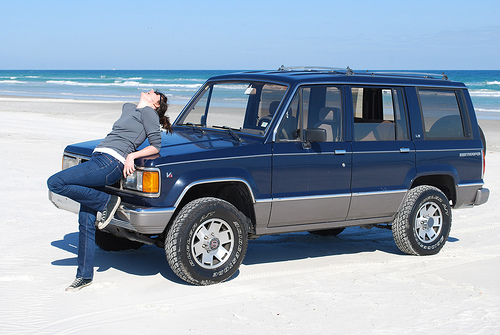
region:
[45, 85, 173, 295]
woman leaning on the hood of a blue vehicle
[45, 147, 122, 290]
blue jeans on a woman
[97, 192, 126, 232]
black shoe on a woman's feet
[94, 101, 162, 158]
gray long sleeve shirt on a woman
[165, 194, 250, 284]
front car wheel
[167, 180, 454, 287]
two car wheels on a blue vehicle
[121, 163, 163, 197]
front car lights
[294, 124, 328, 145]
black rearview mirror on blue vehicle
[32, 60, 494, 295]
blue vehicle and woman on a beach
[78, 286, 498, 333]
sand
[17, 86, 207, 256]
Woman leaning on an SUV.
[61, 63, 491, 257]
The SUV is blue.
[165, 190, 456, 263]
Sand on the tires.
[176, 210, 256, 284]
Writing on the tire.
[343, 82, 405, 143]
The window is down.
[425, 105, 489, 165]
Spare tire on the back.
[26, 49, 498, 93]
The water is blue.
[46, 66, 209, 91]
White foam in the water.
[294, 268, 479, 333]
The sand is white.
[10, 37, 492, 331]
Taken on a beach.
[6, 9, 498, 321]
A beach scene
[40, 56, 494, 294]
A sport utility vehicle is on the beach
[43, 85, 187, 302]
A woman is leaning on the front of the vehicle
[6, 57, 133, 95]
The ocean is in the background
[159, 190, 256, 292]
The suv's front wheel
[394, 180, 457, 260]
This is the rear wheel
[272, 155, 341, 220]
The SUV is blue and gray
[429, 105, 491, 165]
A spare tire is on the rear of the vehicle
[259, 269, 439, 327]
The ground is sand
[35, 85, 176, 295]
The woman is wearing a gray shirt and blue jeans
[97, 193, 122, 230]
shoe on the bumper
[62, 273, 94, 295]
shoe on the sand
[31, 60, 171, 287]
she leans on the jeep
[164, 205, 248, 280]
the front wheel of the jeep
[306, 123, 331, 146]
the side view mirror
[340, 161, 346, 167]
lock on the door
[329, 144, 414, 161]
handles for the car doors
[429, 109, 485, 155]
tire on the trunk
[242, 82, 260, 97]
the mirror on the ceiling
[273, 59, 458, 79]
a roof rack on the hood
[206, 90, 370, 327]
a car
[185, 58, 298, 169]
a car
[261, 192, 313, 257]
a car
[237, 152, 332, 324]
a car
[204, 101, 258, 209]
a car